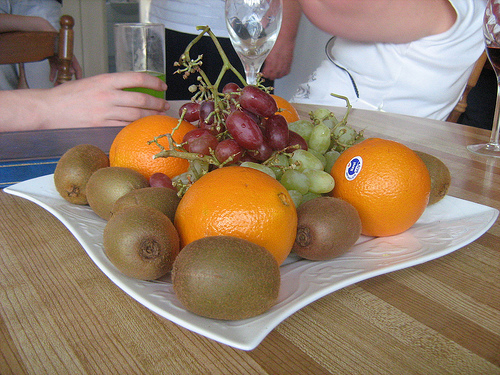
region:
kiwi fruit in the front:
[162, 235, 272, 312]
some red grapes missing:
[174, 57, 291, 153]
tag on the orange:
[348, 148, 370, 182]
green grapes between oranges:
[271, 162, 338, 197]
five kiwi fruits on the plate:
[66, 142, 258, 321]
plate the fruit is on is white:
[290, 243, 499, 306]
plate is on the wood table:
[6, 325, 498, 374]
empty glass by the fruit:
[233, 0, 265, 95]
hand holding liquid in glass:
[111, 16, 161, 117]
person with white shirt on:
[319, 42, 466, 123]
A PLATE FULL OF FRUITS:
[113, 68, 397, 300]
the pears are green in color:
[112, 212, 274, 316]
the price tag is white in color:
[334, 155, 374, 180]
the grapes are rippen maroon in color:
[204, 90, 288, 146]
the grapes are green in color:
[274, 144, 351, 195]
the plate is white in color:
[286, 249, 398, 292]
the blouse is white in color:
[334, 34, 457, 106]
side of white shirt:
[289, 1, 487, 116]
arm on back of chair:
[2, 12, 78, 80]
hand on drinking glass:
[58, 20, 168, 126]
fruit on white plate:
[3, 26, 495, 352]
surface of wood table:
[4, 99, 496, 374]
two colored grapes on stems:
[225, 86, 347, 181]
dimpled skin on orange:
[334, 135, 428, 239]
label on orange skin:
[344, 153, 362, 180]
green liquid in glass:
[120, 70, 166, 101]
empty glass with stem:
[225, 9, 282, 84]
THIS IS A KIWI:
[57, 137, 94, 194]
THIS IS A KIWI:
[79, 168, 139, 199]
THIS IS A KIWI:
[107, 182, 178, 206]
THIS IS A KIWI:
[109, 207, 180, 263]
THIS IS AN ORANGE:
[340, 135, 431, 236]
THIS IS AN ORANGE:
[178, 156, 306, 241]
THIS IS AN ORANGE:
[115, 112, 186, 163]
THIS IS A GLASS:
[114, 21, 166, 70]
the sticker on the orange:
[335, 152, 366, 184]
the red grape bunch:
[170, 75, 316, 174]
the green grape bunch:
[250, 105, 363, 207]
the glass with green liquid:
[110, 20, 172, 114]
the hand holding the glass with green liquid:
[40, 63, 183, 138]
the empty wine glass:
[224, 1, 298, 90]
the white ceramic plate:
[2, 172, 498, 354]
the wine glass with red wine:
[463, 2, 498, 171]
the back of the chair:
[0, 28, 81, 98]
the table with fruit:
[0, 99, 498, 369]